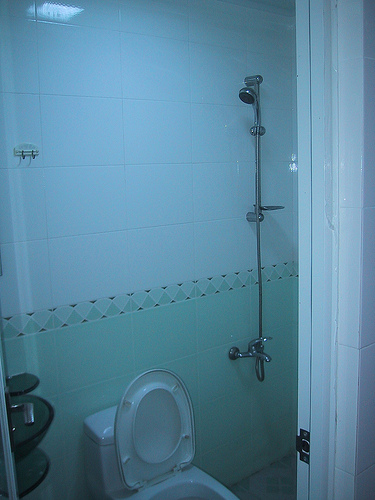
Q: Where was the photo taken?
A: In a bathroom.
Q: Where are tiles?
A: On the wall.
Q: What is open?
A: The door.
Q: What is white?
A: Toilet.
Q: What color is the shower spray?
A: Silver.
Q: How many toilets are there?
A: One.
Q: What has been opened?
A: Toilet seat lid.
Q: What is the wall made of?
A: Tile.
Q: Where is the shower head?
A: On the pole.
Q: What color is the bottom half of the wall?
A: Green.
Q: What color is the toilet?
A: White.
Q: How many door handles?
A: One.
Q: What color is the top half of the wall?
A: White.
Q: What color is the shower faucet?
A: Silver.